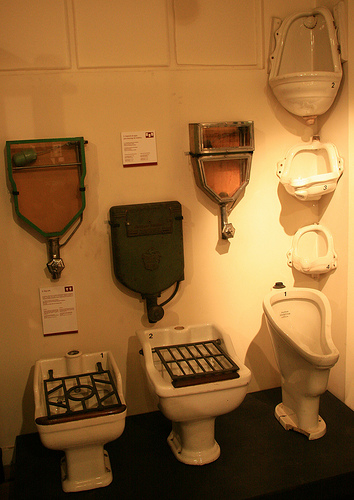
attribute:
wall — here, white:
[66, 24, 238, 125]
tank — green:
[103, 195, 202, 320]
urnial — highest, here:
[258, 7, 349, 128]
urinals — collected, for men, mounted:
[271, 131, 350, 276]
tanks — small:
[3, 97, 272, 304]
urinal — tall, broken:
[250, 278, 343, 446]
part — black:
[70, 368, 121, 424]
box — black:
[258, 445, 338, 487]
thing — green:
[5, 145, 60, 166]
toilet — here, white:
[127, 325, 259, 476]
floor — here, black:
[242, 425, 309, 484]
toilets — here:
[73, 112, 348, 442]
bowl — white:
[279, 297, 337, 365]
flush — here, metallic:
[221, 206, 246, 248]